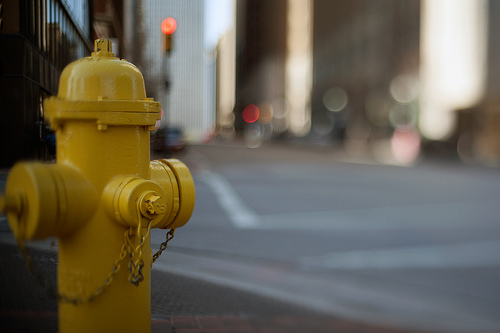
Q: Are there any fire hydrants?
A: Yes, there is a fire hydrant.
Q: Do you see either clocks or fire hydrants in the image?
A: Yes, there is a fire hydrant.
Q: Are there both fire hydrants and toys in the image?
A: No, there is a fire hydrant but no toys.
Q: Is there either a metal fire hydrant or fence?
A: Yes, there is a metal fire hydrant.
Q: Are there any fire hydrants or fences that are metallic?
A: Yes, the fire hydrant is metallic.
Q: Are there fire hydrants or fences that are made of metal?
A: Yes, the fire hydrant is made of metal.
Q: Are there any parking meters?
A: No, there are no parking meters.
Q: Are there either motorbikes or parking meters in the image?
A: No, there are no parking meters or motorbikes.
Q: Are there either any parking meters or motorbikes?
A: No, there are no parking meters or motorbikes.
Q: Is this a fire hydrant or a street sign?
A: This is a fire hydrant.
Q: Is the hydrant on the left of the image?
A: Yes, the hydrant is on the left of the image.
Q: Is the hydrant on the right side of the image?
A: No, the hydrant is on the left of the image.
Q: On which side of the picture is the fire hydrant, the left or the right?
A: The fire hydrant is on the left of the image.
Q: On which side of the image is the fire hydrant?
A: The fire hydrant is on the left of the image.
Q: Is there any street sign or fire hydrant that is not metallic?
A: No, there is a fire hydrant but it is metallic.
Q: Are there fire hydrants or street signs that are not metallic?
A: No, there is a fire hydrant but it is metallic.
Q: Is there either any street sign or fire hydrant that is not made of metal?
A: No, there is a fire hydrant but it is made of metal.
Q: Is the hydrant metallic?
A: Yes, the hydrant is metallic.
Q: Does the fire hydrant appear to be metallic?
A: Yes, the fire hydrant is metallic.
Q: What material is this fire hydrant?
A: The fire hydrant is made of metal.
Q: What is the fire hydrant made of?
A: The fire hydrant is made of metal.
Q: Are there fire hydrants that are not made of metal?
A: No, there is a fire hydrant but it is made of metal.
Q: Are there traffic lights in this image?
A: Yes, there is a traffic light.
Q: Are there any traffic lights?
A: Yes, there is a traffic light.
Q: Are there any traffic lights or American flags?
A: Yes, there is a traffic light.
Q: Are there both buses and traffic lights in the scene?
A: No, there is a traffic light but no buses.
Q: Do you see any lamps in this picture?
A: No, there are no lamps.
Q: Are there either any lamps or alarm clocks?
A: No, there are no lamps or alarm clocks.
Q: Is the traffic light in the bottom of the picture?
A: No, the traffic light is in the top of the image.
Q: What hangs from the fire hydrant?
A: The chain hangs from the fire hydrant.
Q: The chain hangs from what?
A: The chain hangs from the fire hydrant.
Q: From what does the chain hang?
A: The chain hangs from the fire hydrant.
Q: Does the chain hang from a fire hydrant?
A: Yes, the chain hangs from a fire hydrant.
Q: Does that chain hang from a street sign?
A: No, the chain hangs from a fire hydrant.